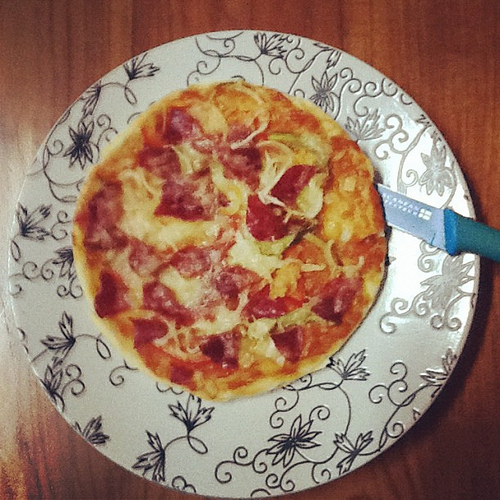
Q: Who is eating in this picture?
A: No one.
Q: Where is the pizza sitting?
A: On the plate.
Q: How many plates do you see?
A: 1.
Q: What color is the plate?
A: Black and white.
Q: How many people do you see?
A: 0.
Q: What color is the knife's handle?
A: Blue.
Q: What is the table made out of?
A: Wood.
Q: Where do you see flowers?
A: On the plate.